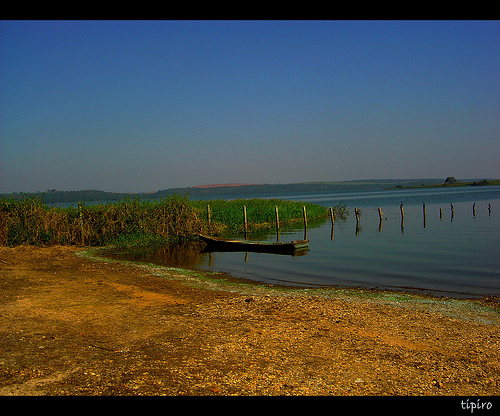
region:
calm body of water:
[194, 187, 494, 300]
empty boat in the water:
[189, 230, 311, 256]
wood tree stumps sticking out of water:
[202, 202, 497, 224]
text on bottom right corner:
[455, 395, 499, 412]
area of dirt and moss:
[1, 299, 493, 398]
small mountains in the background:
[389, 176, 495, 186]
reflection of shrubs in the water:
[119, 244, 206, 272]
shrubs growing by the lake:
[0, 193, 207, 240]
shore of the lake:
[82, 237, 493, 313]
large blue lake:
[179, 180, 497, 305]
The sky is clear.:
[2, 20, 498, 183]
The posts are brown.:
[43, 193, 492, 233]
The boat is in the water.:
[187, 226, 311, 259]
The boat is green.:
[187, 221, 311, 259]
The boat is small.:
[187, 221, 324, 263]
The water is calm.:
[168, 195, 496, 301]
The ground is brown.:
[5, 236, 497, 398]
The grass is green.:
[17, 195, 334, 240]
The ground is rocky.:
[6, 242, 498, 403]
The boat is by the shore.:
[185, 226, 322, 260]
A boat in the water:
[197, 230, 312, 253]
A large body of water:
[50, 181, 495, 286]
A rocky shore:
[2, 247, 493, 408]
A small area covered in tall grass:
[0, 190, 315, 240]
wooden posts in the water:
[76, 200, 492, 220]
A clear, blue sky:
[5, 15, 495, 185]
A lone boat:
[193, 227, 308, 260]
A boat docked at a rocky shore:
[197, 227, 316, 258]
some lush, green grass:
[203, 198, 311, 222]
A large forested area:
[6, 187, 142, 201]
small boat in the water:
[182, 227, 322, 270]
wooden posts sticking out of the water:
[198, 198, 440, 235]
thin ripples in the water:
[262, 257, 499, 294]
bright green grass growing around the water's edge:
[198, 197, 328, 227]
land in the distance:
[35, 173, 393, 205]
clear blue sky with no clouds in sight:
[2, 20, 493, 177]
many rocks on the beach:
[221, 308, 454, 398]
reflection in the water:
[151, 242, 203, 264]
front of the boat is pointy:
[194, 230, 208, 244]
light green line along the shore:
[109, 259, 222, 294]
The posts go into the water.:
[74, 202, 497, 236]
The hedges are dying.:
[13, 196, 203, 238]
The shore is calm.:
[83, 238, 499, 325]